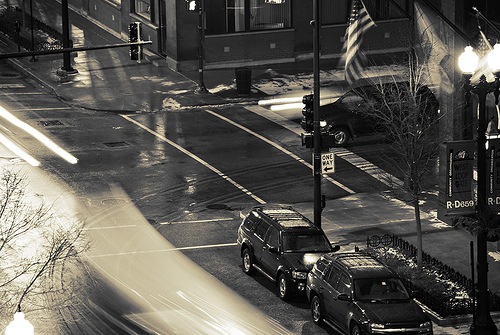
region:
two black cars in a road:
[211, 194, 446, 333]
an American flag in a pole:
[333, 3, 396, 93]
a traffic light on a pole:
[293, 77, 340, 159]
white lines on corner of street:
[116, 108, 353, 207]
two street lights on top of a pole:
[448, 40, 498, 95]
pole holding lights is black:
[463, 86, 495, 333]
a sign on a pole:
[316, 144, 338, 179]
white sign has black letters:
[319, 150, 341, 180]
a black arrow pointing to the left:
[316, 150, 340, 179]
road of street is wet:
[19, 56, 271, 318]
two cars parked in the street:
[232, 202, 430, 332]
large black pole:
[305, 7, 337, 252]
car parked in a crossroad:
[304, 75, 439, 143]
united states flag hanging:
[335, 2, 375, 90]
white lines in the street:
[130, 105, 357, 215]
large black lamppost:
[451, 41, 496, 328]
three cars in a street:
[235, 78, 429, 333]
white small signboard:
[320, 151, 335, 173]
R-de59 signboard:
[442, 137, 497, 219]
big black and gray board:
[200, 26, 302, 92]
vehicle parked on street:
[233, 185, 330, 296]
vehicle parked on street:
[300, 246, 452, 332]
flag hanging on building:
[330, 0, 391, 80]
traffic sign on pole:
[300, 128, 362, 191]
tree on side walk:
[387, 58, 437, 280]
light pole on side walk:
[458, 23, 495, 331]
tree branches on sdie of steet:
[5, 172, 80, 289]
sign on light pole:
[440, 130, 476, 221]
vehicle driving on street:
[325, 70, 440, 132]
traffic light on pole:
[101, 14, 150, 74]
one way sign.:
[311, 152, 356, 189]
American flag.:
[319, 12, 420, 87]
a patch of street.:
[118, 122, 261, 194]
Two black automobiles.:
[226, 205, 444, 333]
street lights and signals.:
[293, 84, 328, 143]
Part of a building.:
[203, 12, 300, 64]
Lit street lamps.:
[435, 28, 499, 102]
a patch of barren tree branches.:
[7, 182, 87, 299]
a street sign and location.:
[438, 201, 485, 211]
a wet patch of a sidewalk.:
[73, 76, 179, 99]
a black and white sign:
[321, 148, 353, 180]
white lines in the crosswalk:
[129, 114, 291, 191]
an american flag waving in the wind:
[342, 0, 379, 85]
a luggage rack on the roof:
[263, 204, 303, 224]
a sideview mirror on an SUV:
[333, 290, 353, 309]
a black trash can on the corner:
[225, 56, 262, 113]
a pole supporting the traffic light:
[26, 42, 138, 54]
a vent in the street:
[96, 137, 148, 160]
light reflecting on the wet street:
[154, 114, 181, 135]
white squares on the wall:
[216, 40, 296, 56]